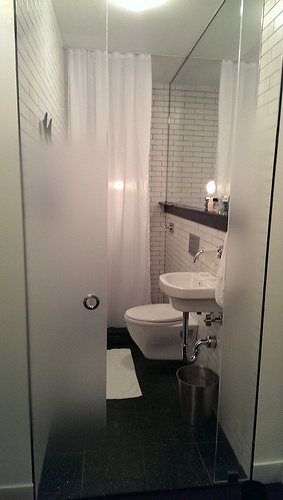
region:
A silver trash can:
[174, 360, 221, 428]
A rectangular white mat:
[105, 344, 144, 401]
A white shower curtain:
[62, 46, 153, 332]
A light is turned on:
[107, 0, 169, 15]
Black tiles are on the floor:
[36, 332, 249, 498]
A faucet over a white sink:
[156, 242, 224, 315]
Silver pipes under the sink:
[158, 268, 223, 365]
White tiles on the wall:
[149, 79, 218, 303]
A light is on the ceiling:
[101, 0, 178, 20]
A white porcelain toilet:
[121, 300, 199, 364]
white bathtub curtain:
[109, 51, 153, 298]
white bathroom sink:
[158, 266, 218, 312]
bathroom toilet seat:
[123, 303, 184, 357]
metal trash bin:
[173, 360, 216, 427]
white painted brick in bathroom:
[153, 83, 166, 198]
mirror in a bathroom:
[165, 64, 228, 194]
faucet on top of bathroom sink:
[191, 243, 220, 267]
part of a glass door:
[239, 27, 252, 484]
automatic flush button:
[186, 233, 198, 254]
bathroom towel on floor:
[108, 346, 139, 402]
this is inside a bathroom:
[17, 87, 255, 369]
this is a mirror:
[23, 169, 246, 369]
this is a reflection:
[13, 284, 232, 423]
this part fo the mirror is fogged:
[31, 293, 111, 408]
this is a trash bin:
[164, 358, 229, 445]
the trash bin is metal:
[169, 370, 206, 415]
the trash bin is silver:
[163, 366, 229, 442]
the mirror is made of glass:
[31, 316, 214, 450]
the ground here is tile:
[120, 425, 202, 486]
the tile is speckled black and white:
[116, 430, 185, 474]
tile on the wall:
[150, 186, 165, 190]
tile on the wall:
[152, 164, 164, 171]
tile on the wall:
[232, 439, 244, 451]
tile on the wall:
[153, 114, 168, 120]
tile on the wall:
[153, 219, 161, 225]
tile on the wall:
[148, 152, 162, 158]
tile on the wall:
[150, 292, 160, 299]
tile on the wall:
[152, 133, 165, 139]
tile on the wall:
[148, 144, 164, 150]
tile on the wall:
[148, 156, 164, 162]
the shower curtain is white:
[65, 45, 151, 332]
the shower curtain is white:
[66, 44, 155, 337]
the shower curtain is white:
[66, 41, 162, 337]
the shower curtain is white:
[64, 31, 159, 335]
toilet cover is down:
[116, 293, 181, 362]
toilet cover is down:
[122, 297, 186, 368]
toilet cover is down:
[131, 308, 196, 365]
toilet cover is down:
[99, 278, 196, 375]